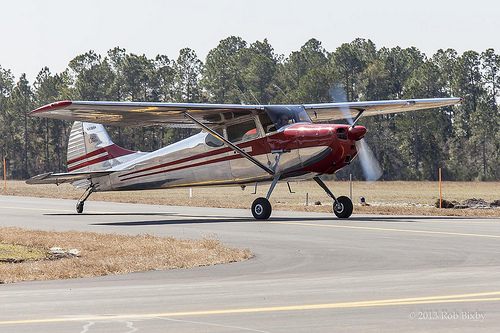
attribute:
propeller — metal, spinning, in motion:
[318, 80, 387, 193]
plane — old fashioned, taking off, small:
[21, 75, 466, 225]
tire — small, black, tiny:
[72, 197, 90, 217]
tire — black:
[247, 196, 277, 222]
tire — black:
[330, 193, 358, 221]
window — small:
[203, 116, 261, 151]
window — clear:
[258, 109, 315, 135]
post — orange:
[432, 164, 449, 211]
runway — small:
[4, 192, 498, 332]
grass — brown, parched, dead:
[1, 176, 499, 275]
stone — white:
[45, 242, 88, 262]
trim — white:
[253, 202, 265, 216]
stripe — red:
[63, 141, 142, 177]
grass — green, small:
[1, 242, 43, 261]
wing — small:
[26, 95, 257, 128]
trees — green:
[0, 32, 499, 187]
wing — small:
[308, 91, 467, 126]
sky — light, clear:
[2, 2, 500, 82]